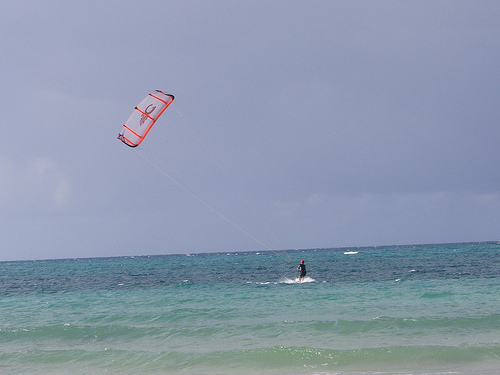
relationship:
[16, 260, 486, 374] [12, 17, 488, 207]
ocean under sky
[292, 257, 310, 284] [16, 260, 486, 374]
man in ocean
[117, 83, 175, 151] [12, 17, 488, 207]
parasail in sky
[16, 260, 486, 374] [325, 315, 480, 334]
ocean has wave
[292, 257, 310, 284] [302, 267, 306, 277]
man wearing wetsuit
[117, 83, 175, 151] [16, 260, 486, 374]
parasail over ocean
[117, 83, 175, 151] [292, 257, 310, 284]
parasail attached to man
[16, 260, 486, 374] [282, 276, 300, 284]
ocean has foam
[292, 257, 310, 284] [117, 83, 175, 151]
man flying parasail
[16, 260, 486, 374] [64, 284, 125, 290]
ocean has wave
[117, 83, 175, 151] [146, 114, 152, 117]
parasail has orange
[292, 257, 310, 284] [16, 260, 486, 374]
man on ocean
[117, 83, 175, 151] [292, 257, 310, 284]
parasail pulling man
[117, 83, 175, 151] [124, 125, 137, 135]
parasail has stripe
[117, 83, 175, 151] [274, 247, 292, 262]
parasail has string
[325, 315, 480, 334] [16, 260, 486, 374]
wave in ocean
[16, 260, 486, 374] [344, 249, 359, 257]
ocean has foam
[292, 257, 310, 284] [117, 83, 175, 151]
man has parasail